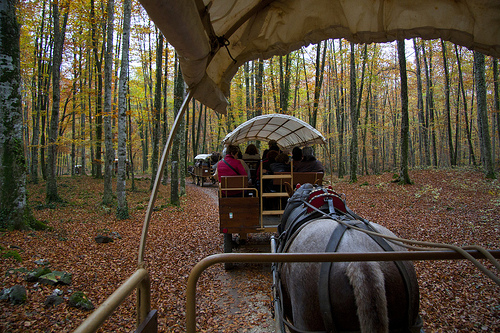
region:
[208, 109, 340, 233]
People riding in a covered wagon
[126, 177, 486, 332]
A brown horse pulling a wagon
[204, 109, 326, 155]
White tarp over wagon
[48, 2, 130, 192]
The trees in the fall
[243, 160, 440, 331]
the horse is wearing a harness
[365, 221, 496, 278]
Reins to the horse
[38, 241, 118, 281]
Leaves that have fallen to the ground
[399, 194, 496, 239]
The leaves are orange and brown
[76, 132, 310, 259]
Riding in covered wagons on a fall day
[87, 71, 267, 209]
A nice ride through the trees in the fall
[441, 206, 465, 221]
part of a tree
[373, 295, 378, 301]
part of a tail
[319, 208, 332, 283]
part of a zebra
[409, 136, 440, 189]
edge of a tree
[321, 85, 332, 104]
part of a branch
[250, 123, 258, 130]
part of a cabin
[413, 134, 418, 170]
edge of a stem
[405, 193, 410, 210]
side of a stem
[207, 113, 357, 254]
the people are in the cart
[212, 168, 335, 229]
the cart is wooden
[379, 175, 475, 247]
the leaves are red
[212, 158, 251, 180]
the shirt is red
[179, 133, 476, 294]
the carts are three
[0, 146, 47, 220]
mould is on the tree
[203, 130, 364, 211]
people are in the cart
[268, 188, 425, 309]
the horse is brown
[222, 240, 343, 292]
the metal is brown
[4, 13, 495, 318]
it is daytime in the city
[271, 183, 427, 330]
dark brown horse with straps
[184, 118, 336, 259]
two horse trolleys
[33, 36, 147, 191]
forest with a lot of trees with yellow and orange leafs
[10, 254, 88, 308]
green moss rocks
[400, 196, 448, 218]
red leafs on ground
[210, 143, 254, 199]
girl with pink jack on with strap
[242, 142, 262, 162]
lady with yellow shirt on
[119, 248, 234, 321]
two dark gold rails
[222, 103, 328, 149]
white canopy on horse trolley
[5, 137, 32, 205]
moss growing on a tree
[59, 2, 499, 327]
horse pulling a cart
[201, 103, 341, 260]
a cart in front a horse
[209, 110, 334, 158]
roof of cart is white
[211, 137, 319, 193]
six people traveling in a cart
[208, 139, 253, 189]
person wears a red top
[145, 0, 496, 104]
roof of the cart is white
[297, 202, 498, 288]
a rope color brown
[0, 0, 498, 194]
trunks of trees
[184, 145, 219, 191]
a cart pulling by a horse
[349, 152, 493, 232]
dead leaves on the ground